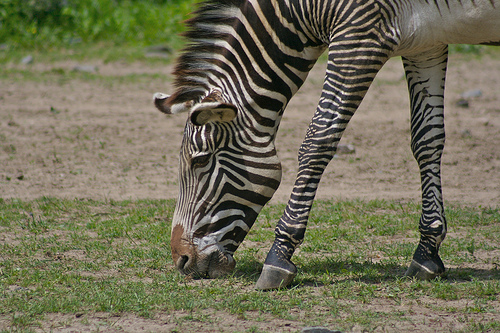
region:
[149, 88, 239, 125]
Ears on a zebra's head.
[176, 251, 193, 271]
Nostril on a zebra's snout.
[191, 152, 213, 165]
A zebra's black eye.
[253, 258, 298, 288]
A zebra's front hoof.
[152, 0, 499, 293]
A zebra eating grass.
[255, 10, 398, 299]
The front leg of a zebra.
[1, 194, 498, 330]
Patches of grass in the dirt.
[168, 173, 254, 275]
The snout of a zebra.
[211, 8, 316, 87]
A striped pattern on a zebra's neck.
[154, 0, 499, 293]
A zebra eats a little grass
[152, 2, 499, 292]
zebra is standing still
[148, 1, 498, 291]
zebra has all legs on the ground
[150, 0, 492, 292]
zebra sniffs the ground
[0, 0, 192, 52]
bushes are in the background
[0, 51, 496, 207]
ground is barren of grass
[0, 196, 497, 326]
grass is patchy on this section of the field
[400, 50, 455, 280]
leg has stripes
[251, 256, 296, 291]
hoof is attached to leg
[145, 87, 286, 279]
head has stripes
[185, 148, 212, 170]
eye belongs to zebra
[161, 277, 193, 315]
green grass on ground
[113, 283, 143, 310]
green grass on ground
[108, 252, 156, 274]
green grass on ground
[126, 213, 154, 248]
green grass on ground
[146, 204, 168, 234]
green grass on ground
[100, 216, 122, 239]
green grass on ground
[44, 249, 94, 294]
green grass on ground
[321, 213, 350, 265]
green grass on ground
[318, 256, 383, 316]
green grass on ground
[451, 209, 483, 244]
green grass on ground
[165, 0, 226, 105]
the mane of the zebra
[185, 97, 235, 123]
the ear of the zebra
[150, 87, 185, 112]
the ear of the zebra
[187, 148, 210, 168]
the eye of the zebra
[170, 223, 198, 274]
the nose of the zebra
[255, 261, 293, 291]
a hoof of the zebra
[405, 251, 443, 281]
the hoof of the zebra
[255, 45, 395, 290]
the zebra's front leg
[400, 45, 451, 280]
the zebra's front leg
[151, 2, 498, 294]
a zebra grazing on grass